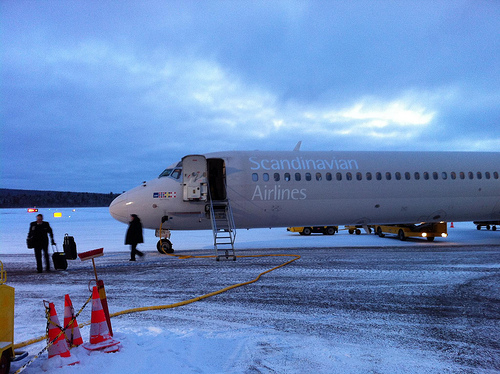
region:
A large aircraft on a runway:
[107, 133, 497, 265]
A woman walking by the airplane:
[119, 207, 152, 266]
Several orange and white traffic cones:
[41, 290, 129, 365]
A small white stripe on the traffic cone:
[86, 318, 118, 337]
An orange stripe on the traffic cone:
[88, 308, 109, 325]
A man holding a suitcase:
[22, 212, 67, 275]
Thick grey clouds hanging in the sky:
[241, 6, 454, 95]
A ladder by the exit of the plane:
[208, 202, 247, 260]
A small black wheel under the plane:
[152, 237, 178, 255]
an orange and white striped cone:
[89, 283, 116, 350]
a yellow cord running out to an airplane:
[10, 221, 300, 350]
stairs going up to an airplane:
[204, 186, 239, 260]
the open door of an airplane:
[179, 153, 228, 206]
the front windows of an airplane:
[159, 168, 183, 180]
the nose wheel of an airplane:
[154, 236, 176, 256]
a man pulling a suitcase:
[26, 213, 58, 270]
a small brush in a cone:
[74, 244, 107, 287]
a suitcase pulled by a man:
[51, 239, 68, 270]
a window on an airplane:
[283, 169, 292, 183]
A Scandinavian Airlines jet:
[107, 120, 498, 257]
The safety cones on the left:
[44, 273, 118, 365]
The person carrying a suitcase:
[24, 212, 66, 274]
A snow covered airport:
[0, 209, 499, 371]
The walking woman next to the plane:
[122, 202, 149, 259]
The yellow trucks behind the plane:
[286, 221, 453, 238]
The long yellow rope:
[1, 213, 301, 360]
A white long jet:
[111, 151, 498, 261]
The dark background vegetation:
[0, 189, 122, 206]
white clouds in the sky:
[350, 102, 418, 129]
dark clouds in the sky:
[276, 10, 426, 91]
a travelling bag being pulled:
[51, 245, 68, 268]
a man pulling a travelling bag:
[24, 210, 66, 273]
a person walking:
[119, 212, 145, 261]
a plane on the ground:
[123, 132, 498, 238]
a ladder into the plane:
[206, 194, 240, 263]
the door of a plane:
[201, 157, 231, 207]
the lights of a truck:
[418, 230, 449, 238]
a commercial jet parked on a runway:
[11, 54, 497, 299]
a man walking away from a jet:
[14, 192, 114, 297]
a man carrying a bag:
[22, 206, 73, 275]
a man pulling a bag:
[15, 205, 85, 273]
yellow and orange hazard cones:
[33, 278, 125, 360]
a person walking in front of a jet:
[115, 209, 158, 264]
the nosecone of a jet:
[102, 191, 127, 223]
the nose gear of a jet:
[151, 223, 184, 258]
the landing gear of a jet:
[151, 222, 175, 257]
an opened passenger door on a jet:
[178, 150, 211, 202]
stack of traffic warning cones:
[43, 282, 122, 367]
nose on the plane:
[93, 175, 170, 232]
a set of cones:
[33, 272, 111, 372]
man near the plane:
[16, 199, 63, 271]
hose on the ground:
[50, 217, 288, 342]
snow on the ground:
[33, 243, 495, 371]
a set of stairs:
[198, 194, 249, 269]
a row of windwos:
[239, 165, 494, 195]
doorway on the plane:
[203, 156, 231, 200]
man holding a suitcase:
[10, 202, 72, 279]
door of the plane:
[176, 146, 208, 204]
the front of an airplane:
[110, 146, 498, 258]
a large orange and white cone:
[80, 287, 116, 355]